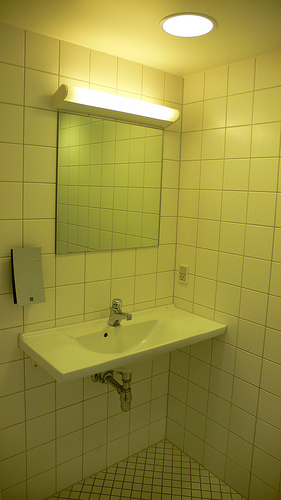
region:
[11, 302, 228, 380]
white bathroom sink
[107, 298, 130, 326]
silver faucet on the sink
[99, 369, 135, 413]
metal pipes under the sink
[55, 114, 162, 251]
glass mirror over the sink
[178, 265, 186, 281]
electrical outlet by the sink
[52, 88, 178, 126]
light on wall over the sink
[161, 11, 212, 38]
round light in the ceiling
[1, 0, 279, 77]
white ceiling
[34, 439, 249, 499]
small square tile floor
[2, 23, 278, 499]
square white tile on walls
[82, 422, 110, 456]
This is a tile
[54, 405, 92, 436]
This is a tile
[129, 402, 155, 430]
This is a tile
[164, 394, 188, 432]
This is a tile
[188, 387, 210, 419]
This is a tile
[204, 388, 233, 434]
This is a tile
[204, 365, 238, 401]
This is a tile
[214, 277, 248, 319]
This is a tile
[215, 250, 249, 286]
This is a tile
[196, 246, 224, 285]
This is a tile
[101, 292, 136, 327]
faucet of a sink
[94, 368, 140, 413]
pipes under sink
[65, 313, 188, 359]
a sink of a toilet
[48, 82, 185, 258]
mirrors mounted on restroom wall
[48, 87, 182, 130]
beam of fluorescent light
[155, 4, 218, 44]
light mounted on ceiling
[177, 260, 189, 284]
power outlet mounted on wall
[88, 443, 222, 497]
floor tiles of restroom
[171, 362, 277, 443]
restroom wall tiles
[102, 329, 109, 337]
drainage hole of a sink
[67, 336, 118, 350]
a sink in the bathroom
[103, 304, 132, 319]
a tap above the sink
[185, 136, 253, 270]
tiles on the wall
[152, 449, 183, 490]
tiles on the floor of the room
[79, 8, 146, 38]
right grey roof in the room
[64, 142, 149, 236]
the mirror on the wall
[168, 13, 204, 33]
the light bulb on the ceiling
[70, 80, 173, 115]
florescent tube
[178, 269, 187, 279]
a socket on the wall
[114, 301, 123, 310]
the knob of a tap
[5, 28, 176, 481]
This is a wall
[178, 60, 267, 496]
This is a wall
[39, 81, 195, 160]
This is a light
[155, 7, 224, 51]
This is a light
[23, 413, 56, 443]
This is a tile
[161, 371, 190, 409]
This is a tile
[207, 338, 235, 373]
This is a tile